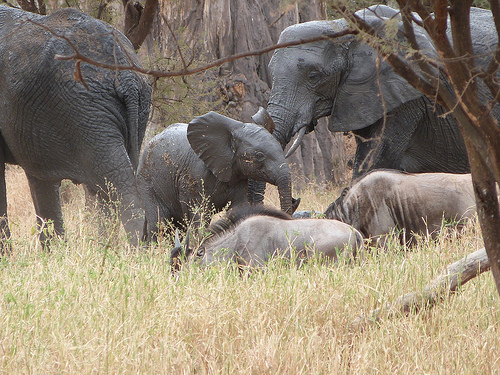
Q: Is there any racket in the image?
A: No, there are no rackets.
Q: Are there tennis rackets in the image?
A: No, there are no tennis rackets.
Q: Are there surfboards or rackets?
A: No, there are no rackets or surfboards.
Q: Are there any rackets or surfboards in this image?
A: No, there are no rackets or surfboards.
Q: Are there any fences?
A: No, there are no fences.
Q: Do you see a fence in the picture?
A: No, there are no fences.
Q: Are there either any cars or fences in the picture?
A: No, there are no fences or cars.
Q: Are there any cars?
A: No, there are no cars.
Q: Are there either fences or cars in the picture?
A: No, there are no cars or fences.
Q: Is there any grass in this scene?
A: Yes, there is grass.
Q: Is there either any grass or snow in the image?
A: Yes, there is grass.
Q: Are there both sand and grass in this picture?
A: No, there is grass but no sand.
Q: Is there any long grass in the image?
A: Yes, there is long grass.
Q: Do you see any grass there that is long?
A: Yes, there is grass that is long.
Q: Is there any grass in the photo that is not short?
A: Yes, there is long grass.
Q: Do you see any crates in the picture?
A: No, there are no crates.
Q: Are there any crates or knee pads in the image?
A: No, there are no crates or knee pads.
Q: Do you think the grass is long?
A: Yes, the grass is long.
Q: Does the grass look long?
A: Yes, the grass is long.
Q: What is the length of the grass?
A: The grass is long.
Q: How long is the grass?
A: The grass is long.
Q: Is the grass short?
A: No, the grass is long.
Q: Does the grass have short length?
A: No, the grass is long.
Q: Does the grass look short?
A: No, the grass is long.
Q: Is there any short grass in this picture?
A: No, there is grass but it is long.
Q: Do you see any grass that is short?
A: No, there is grass but it is long.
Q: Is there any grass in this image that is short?
A: No, there is grass but it is long.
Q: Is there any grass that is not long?
A: No, there is grass but it is long.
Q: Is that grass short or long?
A: The grass is long.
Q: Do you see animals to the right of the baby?
A: Yes, there is an animal to the right of the baby.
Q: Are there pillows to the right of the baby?
A: No, there is an animal to the right of the baby.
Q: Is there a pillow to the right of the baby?
A: No, there is an animal to the right of the baby.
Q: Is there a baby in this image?
A: Yes, there is a baby.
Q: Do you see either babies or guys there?
A: Yes, there is a baby.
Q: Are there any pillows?
A: No, there are no pillows.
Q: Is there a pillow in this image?
A: No, there are no pillows.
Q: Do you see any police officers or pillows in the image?
A: No, there are no pillows or police officers.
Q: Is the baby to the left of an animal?
A: Yes, the baby is to the left of an animal.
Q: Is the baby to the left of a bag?
A: No, the baby is to the left of an animal.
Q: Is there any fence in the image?
A: No, there are no fences.